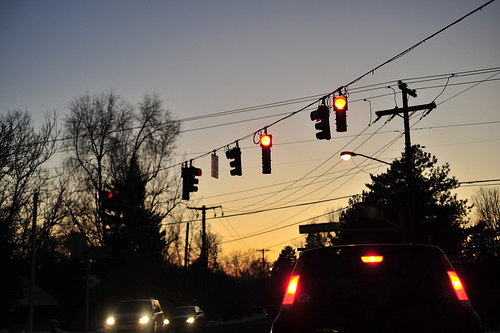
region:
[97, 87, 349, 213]
illuminated red traffic lights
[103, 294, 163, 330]
a silver van with illuminated head lights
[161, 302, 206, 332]
a car with illuminated head lights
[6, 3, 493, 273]
a darkening sky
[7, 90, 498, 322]
trees line the roads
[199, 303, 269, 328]
white snow on the road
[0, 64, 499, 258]
utility lines are overhead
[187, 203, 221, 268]
tall wooden utility pole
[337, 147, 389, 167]
an illuminated street light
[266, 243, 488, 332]
illuminated tail lights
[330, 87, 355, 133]
traffic light on a pole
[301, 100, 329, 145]
traffic light on a pole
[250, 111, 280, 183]
traffic light on a pole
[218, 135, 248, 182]
traffic light on a pole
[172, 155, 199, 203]
traffic light on a pole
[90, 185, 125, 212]
traffic light on a pole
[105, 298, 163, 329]
car on a street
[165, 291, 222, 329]
car on a street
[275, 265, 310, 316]
tail light on a car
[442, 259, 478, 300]
tail on a car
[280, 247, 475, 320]
Car's break lights are on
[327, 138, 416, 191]
a lit street light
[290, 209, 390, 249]
a silhoutte of a street sign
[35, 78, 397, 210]
Row of traffic lights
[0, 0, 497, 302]
sun setting in the distance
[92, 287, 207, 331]
two cars in a row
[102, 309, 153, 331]
Bright lit head lights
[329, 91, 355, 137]
traffic light lit up red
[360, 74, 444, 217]
Utility Pole with wires attached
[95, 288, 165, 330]
White SUV with it's headlights on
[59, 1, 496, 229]
multiple traffic lights on a wire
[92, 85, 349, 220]
traffic lights face all different directions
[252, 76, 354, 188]
two featured lights shine red, but look yellow in photograph's the smoggy dusk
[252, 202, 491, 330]
three suv or truck tail/brakelights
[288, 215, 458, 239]
bicycle, or other sort of carrier, rack atop vehicle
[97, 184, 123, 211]
a red light nearly hidden amongst the trees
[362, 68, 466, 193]
a large old power/telephone pole with many connected wires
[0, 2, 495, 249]
a wire-filled dusky [sub]urban sky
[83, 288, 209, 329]
two sets of headlights, bright white, & turned on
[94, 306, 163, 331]
the first headlights are bright & fuzzy as the sun sets & turns the sky from orange to grey to darkness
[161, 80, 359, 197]
traffic lights hanging above street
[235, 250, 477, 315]
lights on the vehicle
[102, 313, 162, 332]
lights on front of vehicle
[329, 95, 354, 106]
lit light on traffic lights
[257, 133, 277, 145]
lit light on traffic lights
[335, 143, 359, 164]
street light over the street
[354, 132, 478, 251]
tree near traffic lights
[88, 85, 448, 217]
mass of power lines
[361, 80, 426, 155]
pole to string power lines from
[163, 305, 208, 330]
vehicle on the road